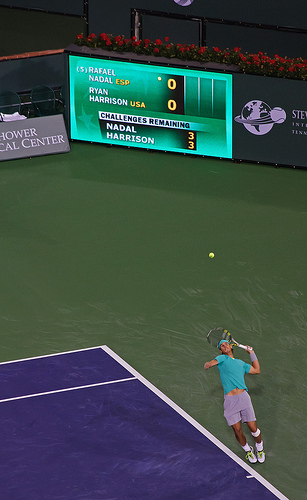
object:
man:
[204, 339, 266, 463]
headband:
[218, 339, 230, 349]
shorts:
[223, 391, 256, 425]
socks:
[242, 443, 251, 452]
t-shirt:
[215, 355, 251, 393]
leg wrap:
[251, 428, 261, 438]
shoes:
[245, 441, 266, 462]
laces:
[245, 452, 264, 458]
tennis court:
[1, 345, 288, 500]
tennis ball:
[208, 251, 215, 258]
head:
[218, 340, 233, 354]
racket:
[207, 326, 253, 351]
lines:
[0, 345, 137, 401]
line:
[138, 376, 287, 500]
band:
[250, 353, 257, 364]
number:
[167, 79, 176, 89]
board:
[68, 55, 234, 160]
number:
[167, 100, 175, 111]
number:
[187, 128, 194, 141]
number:
[187, 142, 195, 150]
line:
[1, 378, 140, 403]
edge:
[1, 344, 139, 380]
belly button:
[230, 388, 241, 394]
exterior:
[1, 140, 307, 499]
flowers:
[76, 32, 307, 79]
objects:
[1, 86, 67, 120]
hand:
[245, 345, 253, 353]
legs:
[232, 421, 257, 464]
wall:
[65, 50, 306, 168]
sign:
[0, 115, 72, 161]